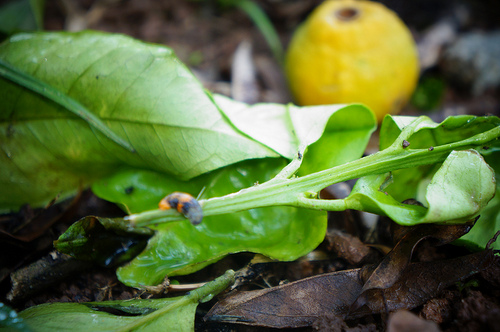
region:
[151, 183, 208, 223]
An orange and black caterpillar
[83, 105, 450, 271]
An orange and black caterpillar resting on a leaf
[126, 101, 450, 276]
An orange and black caterpillar in a leaf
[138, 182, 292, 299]
An orange and black caterpillar on a green fallen leaf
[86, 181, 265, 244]
A caterpillar on a leaf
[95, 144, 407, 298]
A caterpillar on a fallen leaf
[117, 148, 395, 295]
A caterpillar on a green fallen leaf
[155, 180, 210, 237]
caterpillar on a leaf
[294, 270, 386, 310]
dead leaves on the ground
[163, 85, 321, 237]
green leaves on the ground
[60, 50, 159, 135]
green veins on a leaf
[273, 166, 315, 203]
green stem on a leaf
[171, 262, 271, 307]
leaves on the forrest floor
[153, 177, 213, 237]
blurry bug on a leaf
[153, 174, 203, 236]
orange and black bug on plant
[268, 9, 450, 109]
round, yellow fruit on plant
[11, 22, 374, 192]
large green leaves on plant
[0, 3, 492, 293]
fluffy green leaves of plant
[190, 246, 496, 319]
brown dead leaves on ground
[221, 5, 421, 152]
stem of fruit plant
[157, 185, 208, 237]
small insect with black and orange stripes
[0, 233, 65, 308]
dried tip of stem on plant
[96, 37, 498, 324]
stem broken from plant with three leaves on it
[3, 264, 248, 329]
one leaf broken off of plant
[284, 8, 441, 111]
bright yellow lemon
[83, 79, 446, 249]
bright green leaves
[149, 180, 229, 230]
small bug on a green leaf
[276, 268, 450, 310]
brown leaves on the ground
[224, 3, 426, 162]
yellow and green objects on the ground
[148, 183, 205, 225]
small striped bug on a leaf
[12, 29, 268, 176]
big green leaf on the ground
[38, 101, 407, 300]
bug out in nature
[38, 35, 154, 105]
veins on a leaf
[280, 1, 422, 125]
bright yellow lemon on leaves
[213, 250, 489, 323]
brown leaves laying on ground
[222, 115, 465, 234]
green leaves laying on ground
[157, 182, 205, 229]
orange and black bug on green leaf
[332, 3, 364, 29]
hole on top of yellow lemon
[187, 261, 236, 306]
stem of green leaf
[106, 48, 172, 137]
veins on green leaf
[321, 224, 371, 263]
piece of bark laying on ground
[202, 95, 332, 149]
suns reflection on green leaf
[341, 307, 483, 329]
ground with leaves on it